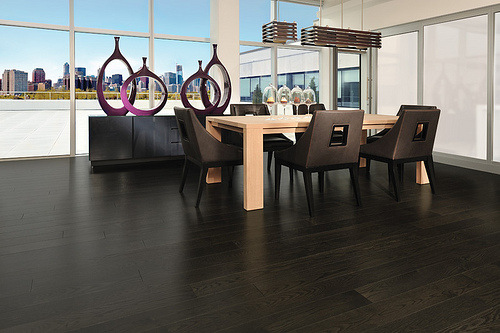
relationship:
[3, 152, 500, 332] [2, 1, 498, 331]
floor in room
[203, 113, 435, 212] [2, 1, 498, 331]
table in room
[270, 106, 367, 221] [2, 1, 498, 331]
chair in room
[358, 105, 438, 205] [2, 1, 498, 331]
chair in room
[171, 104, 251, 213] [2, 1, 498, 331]
chair in room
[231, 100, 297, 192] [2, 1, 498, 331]
chair in room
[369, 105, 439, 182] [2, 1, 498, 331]
chair in room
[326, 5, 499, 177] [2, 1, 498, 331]
wall in room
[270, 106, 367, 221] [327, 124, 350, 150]
chair has hole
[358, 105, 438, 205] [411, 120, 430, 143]
chair has hole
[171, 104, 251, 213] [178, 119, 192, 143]
chair has hole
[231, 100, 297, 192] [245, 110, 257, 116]
chair has hole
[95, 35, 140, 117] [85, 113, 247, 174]
vase on table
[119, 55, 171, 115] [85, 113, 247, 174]
vase on table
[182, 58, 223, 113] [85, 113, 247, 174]
vase on table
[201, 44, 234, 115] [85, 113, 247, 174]
vase on table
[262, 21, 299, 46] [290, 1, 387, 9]
light on ceiling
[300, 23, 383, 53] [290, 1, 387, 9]
light on ceiling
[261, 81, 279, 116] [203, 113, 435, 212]
decoration on table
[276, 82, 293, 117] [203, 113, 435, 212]
decoration on table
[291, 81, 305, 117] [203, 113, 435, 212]
decoration on table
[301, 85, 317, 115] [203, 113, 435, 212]
decoration on table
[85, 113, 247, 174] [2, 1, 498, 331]
table in room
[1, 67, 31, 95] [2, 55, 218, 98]
building in background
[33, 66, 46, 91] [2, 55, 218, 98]
building in background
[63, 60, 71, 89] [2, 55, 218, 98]
building in background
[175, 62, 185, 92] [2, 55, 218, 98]
building in background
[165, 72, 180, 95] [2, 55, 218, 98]
building in background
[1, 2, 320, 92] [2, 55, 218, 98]
sky in background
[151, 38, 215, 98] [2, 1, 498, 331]
window in room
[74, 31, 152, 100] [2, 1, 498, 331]
window in room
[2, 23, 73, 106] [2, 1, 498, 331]
window in room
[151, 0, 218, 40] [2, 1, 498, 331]
window in room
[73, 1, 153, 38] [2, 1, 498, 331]
window in room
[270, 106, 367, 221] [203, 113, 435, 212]
chair at table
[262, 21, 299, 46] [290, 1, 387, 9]
light hangs from ceiling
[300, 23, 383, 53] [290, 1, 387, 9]
light hangs from ceiling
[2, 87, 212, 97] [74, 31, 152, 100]
railing outside window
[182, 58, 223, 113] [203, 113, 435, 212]
vase on table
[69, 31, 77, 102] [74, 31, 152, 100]
post next to window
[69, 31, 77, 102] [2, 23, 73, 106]
post next to window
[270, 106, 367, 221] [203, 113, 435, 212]
chair next to table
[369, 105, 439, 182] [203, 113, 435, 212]
chair next to table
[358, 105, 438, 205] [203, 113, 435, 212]
chair next to table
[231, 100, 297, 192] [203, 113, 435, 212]
chair next to table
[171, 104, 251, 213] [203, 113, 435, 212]
chair next to table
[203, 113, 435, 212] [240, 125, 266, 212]
table has leg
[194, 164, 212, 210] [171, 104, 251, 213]
leg on chair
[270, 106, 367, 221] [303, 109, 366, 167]
chair has back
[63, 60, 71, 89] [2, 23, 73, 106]
building outside window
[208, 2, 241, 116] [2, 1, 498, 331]
pillar in room